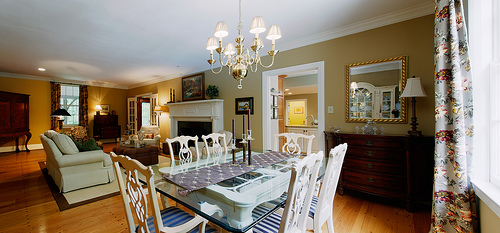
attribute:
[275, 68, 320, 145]
door frame — white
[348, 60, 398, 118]
mirror — gold, metal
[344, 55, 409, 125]
frame — mirror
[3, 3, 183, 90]
ceiling — white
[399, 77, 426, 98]
lampshade — white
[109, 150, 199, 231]
chair — white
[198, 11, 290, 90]
chandelier — bronze, hanging